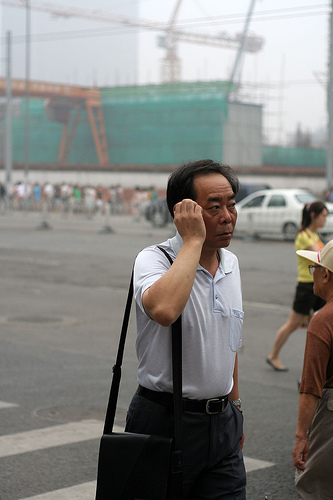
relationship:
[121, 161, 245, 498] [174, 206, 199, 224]
man on phone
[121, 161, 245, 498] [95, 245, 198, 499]
man with satchel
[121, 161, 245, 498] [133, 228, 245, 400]
man in shirt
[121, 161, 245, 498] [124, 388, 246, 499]
man in pants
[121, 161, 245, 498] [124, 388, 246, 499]
man has pants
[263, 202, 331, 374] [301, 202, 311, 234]
woman with pony-tail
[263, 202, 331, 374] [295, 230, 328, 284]
girl in shirt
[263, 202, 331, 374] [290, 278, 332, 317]
woman in skirt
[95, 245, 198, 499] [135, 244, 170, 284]
case over shoulder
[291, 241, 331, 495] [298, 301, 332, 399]
man has shirt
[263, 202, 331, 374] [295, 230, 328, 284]
woman has shirt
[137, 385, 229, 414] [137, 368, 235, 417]
belt on waist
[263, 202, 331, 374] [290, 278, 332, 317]
woman has skirt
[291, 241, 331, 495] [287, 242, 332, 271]
man wearing cap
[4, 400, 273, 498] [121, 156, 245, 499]
lines for man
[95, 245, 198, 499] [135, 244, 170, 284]
satchel on shoulder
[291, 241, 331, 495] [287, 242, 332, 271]
man with hat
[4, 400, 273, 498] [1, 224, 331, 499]
lines on road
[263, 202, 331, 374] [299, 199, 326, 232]
woman has hair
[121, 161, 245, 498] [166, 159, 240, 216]
man has hair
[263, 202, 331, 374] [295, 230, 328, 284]
woman in shirt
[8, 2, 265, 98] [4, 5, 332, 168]
crane in area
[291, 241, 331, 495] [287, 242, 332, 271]
man with cap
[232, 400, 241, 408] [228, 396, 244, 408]
watch on wrist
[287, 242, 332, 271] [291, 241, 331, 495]
cap worn man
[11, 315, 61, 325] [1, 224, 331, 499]
hole in street